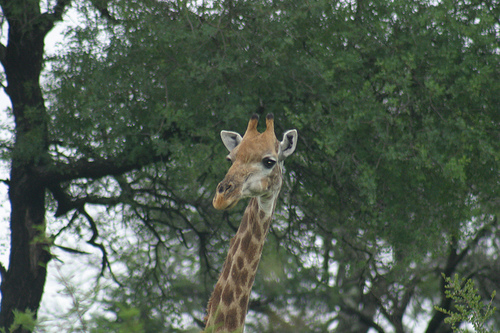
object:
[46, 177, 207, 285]
branch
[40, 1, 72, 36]
branch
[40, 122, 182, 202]
branch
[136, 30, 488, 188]
tree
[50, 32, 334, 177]
branch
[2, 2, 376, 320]
tree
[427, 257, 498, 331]
leaves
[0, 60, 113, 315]
trunk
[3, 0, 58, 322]
tree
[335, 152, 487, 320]
tree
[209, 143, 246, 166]
eyes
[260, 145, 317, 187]
eyes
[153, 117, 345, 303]
giraffe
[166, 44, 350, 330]
giraffe/trees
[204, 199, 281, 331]
neck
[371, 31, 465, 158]
branch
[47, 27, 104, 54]
clouds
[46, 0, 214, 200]
trees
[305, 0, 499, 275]
trees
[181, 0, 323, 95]
trees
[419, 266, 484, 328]
plant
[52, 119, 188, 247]
branches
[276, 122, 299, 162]
ear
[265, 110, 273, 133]
horn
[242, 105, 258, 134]
horn